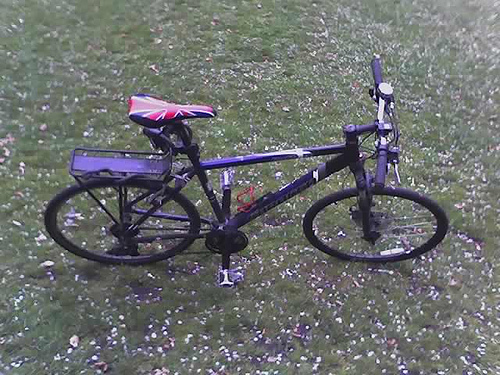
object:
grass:
[51, 93, 95, 135]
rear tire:
[41, 177, 201, 266]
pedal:
[215, 265, 244, 290]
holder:
[234, 183, 259, 214]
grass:
[209, 15, 306, 73]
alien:
[126, 92, 217, 129]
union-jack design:
[127, 93, 210, 122]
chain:
[117, 225, 249, 255]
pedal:
[219, 167, 233, 188]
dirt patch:
[127, 274, 163, 304]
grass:
[337, 311, 498, 373]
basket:
[64, 147, 173, 183]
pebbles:
[66, 335, 79, 350]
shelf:
[66, 145, 175, 241]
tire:
[303, 184, 450, 264]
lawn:
[236, 344, 306, 375]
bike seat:
[127, 92, 218, 129]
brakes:
[374, 144, 402, 190]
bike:
[41, 56, 449, 267]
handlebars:
[369, 58, 403, 189]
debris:
[210, 265, 247, 291]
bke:
[104, 220, 250, 258]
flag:
[127, 93, 218, 122]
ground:
[399, 1, 498, 80]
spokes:
[67, 179, 193, 260]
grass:
[23, 276, 210, 372]